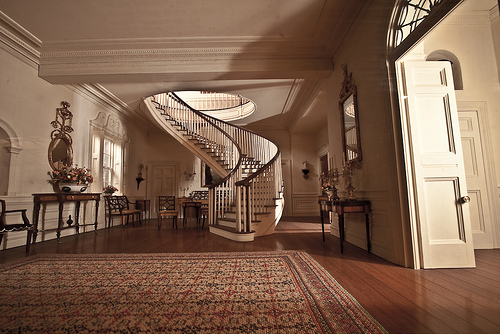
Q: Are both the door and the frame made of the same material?
A: No, the door is made of wood and the frame is made of metal.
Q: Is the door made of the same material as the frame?
A: No, the door is made of wood and the frame is made of metal.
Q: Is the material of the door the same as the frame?
A: No, the door is made of wood and the frame is made of metal.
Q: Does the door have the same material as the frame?
A: No, the door is made of wood and the frame is made of metal.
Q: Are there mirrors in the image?
A: Yes, there is a mirror.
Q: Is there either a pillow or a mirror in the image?
A: Yes, there is a mirror.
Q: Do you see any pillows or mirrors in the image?
A: Yes, there is a mirror.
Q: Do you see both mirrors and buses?
A: No, there is a mirror but no buses.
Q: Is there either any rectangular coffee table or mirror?
A: Yes, there is a rectangular mirror.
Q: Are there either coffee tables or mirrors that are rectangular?
A: Yes, the mirror is rectangular.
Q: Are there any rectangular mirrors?
A: Yes, there is a rectangular mirror.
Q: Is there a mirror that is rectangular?
A: Yes, there is a mirror that is rectangular.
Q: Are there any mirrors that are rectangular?
A: Yes, there is a mirror that is rectangular.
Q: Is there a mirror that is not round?
A: Yes, there is a rectangular mirror.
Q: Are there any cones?
A: No, there are no cones.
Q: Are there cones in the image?
A: No, there are no cones.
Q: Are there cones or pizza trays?
A: No, there are no cones or pizza trays.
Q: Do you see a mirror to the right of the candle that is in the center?
A: Yes, there is a mirror to the right of the candle.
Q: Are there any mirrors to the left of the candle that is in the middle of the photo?
A: No, the mirror is to the right of the candle.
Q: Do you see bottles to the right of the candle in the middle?
A: No, there is a mirror to the right of the candle.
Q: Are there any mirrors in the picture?
A: Yes, there is a mirror.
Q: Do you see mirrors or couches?
A: Yes, there is a mirror.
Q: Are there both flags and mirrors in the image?
A: No, there is a mirror but no flags.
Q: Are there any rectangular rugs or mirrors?
A: Yes, there is a rectangular mirror.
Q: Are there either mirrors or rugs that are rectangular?
A: Yes, the mirror is rectangular.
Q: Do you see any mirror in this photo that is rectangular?
A: Yes, there is a rectangular mirror.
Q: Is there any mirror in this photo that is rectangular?
A: Yes, there is a mirror that is rectangular.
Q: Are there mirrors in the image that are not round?
A: Yes, there is a rectangular mirror.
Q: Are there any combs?
A: No, there are no combs.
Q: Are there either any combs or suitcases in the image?
A: No, there are no combs or suitcases.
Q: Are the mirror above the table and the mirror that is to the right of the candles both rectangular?
A: Yes, both the mirror and the mirror are rectangular.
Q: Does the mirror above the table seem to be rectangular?
A: Yes, the mirror is rectangular.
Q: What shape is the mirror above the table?
A: The mirror is rectangular.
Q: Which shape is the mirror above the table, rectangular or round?
A: The mirror is rectangular.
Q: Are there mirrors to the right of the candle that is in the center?
A: Yes, there is a mirror to the right of the candle.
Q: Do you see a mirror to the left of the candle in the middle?
A: No, the mirror is to the right of the candle.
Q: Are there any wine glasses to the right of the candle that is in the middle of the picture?
A: No, there is a mirror to the right of the candle.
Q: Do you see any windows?
A: Yes, there is a window.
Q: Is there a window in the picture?
A: Yes, there is a window.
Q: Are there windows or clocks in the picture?
A: Yes, there is a window.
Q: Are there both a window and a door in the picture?
A: Yes, there are both a window and a door.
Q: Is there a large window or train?
A: Yes, there is a large window.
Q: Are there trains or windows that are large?
A: Yes, the window is large.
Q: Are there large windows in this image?
A: Yes, there is a large window.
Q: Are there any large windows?
A: Yes, there is a large window.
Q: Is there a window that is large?
A: Yes, there is a window that is large.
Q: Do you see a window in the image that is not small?
A: Yes, there is a large window.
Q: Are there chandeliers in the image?
A: No, there are no chandeliers.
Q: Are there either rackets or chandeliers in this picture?
A: No, there are no chandeliers or rackets.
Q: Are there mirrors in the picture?
A: Yes, there is a mirror.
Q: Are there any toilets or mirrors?
A: Yes, there is a mirror.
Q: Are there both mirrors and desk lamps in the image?
A: No, there is a mirror but no desk lamps.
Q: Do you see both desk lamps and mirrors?
A: No, there is a mirror but no desk lamps.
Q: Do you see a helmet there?
A: No, there are no helmets.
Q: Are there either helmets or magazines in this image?
A: No, there are no helmets or magazines.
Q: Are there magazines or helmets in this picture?
A: No, there are no helmets or magazines.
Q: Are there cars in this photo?
A: No, there are no cars.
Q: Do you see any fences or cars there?
A: No, there are no cars or fences.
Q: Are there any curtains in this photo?
A: No, there are no curtains.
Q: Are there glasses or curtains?
A: No, there are no curtains or glasses.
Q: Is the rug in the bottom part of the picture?
A: Yes, the rug is in the bottom of the image.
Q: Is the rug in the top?
A: No, the rug is in the bottom of the image.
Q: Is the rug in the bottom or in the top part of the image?
A: The rug is in the bottom of the image.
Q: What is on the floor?
A: The rug is on the floor.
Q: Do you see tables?
A: Yes, there is a table.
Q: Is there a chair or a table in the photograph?
A: Yes, there is a table.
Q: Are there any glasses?
A: No, there are no glasses.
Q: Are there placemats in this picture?
A: No, there are no placemats.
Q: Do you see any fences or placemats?
A: No, there are no placemats or fences.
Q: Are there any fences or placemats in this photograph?
A: No, there are no placemats or fences.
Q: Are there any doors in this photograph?
A: Yes, there is a door.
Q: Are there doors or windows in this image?
A: Yes, there is a door.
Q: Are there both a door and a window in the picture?
A: Yes, there are both a door and a window.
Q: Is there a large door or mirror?
A: Yes, there is a large door.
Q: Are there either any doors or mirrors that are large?
A: Yes, the door is large.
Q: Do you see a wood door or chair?
A: Yes, there is a wood door.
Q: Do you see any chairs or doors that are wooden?
A: Yes, the door is wooden.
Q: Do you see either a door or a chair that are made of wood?
A: Yes, the door is made of wood.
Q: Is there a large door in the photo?
A: Yes, there is a large door.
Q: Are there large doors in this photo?
A: Yes, there is a large door.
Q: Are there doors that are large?
A: Yes, there is a door that is large.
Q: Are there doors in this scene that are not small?
A: Yes, there is a large door.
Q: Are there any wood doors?
A: Yes, there is a wood door.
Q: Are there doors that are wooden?
A: Yes, there is a door that is wooden.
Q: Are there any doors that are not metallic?
A: Yes, there is a wooden door.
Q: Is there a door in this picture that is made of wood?
A: Yes, there is a door that is made of wood.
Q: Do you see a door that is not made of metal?
A: Yes, there is a door that is made of wood.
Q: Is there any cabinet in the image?
A: No, there are no cabinets.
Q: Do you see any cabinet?
A: No, there are no cabinets.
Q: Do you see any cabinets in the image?
A: No, there are no cabinets.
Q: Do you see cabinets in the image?
A: No, there are no cabinets.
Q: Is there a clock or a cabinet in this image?
A: No, there are no cabinets or clocks.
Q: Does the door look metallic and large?
A: No, the door is large but wooden.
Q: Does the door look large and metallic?
A: No, the door is large but wooden.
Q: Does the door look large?
A: Yes, the door is large.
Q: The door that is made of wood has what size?
A: The door is large.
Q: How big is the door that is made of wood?
A: The door is large.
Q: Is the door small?
A: No, the door is large.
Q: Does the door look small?
A: No, the door is large.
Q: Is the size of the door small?
A: No, the door is large.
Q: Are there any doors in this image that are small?
A: No, there is a door but it is large.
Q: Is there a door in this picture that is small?
A: No, there is a door but it is large.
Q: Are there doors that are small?
A: No, there is a door but it is large.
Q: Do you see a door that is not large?
A: No, there is a door but it is large.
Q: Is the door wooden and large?
A: Yes, the door is wooden and large.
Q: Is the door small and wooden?
A: No, the door is wooden but large.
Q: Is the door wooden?
A: Yes, the door is wooden.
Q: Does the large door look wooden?
A: Yes, the door is wooden.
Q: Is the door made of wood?
A: Yes, the door is made of wood.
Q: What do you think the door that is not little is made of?
A: The door is made of wood.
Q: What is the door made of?
A: The door is made of wood.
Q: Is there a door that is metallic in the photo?
A: No, there is a door but it is wooden.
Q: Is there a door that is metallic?
A: No, there is a door but it is wooden.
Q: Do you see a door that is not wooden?
A: No, there is a door but it is wooden.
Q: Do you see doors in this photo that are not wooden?
A: No, there is a door but it is wooden.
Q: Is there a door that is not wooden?
A: No, there is a door but it is wooden.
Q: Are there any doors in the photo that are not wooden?
A: No, there is a door but it is wooden.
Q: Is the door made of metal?
A: No, the door is made of wood.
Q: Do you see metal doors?
A: No, there is a door but it is made of wood.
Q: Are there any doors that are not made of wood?
A: No, there is a door but it is made of wood.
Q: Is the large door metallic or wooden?
A: The door is wooden.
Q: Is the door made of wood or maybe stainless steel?
A: The door is made of wood.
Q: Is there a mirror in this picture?
A: Yes, there is a mirror.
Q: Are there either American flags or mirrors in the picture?
A: Yes, there is a mirror.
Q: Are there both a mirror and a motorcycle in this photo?
A: No, there is a mirror but no motorcycles.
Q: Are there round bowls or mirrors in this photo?
A: Yes, there is a round mirror.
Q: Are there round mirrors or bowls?
A: Yes, there is a round mirror.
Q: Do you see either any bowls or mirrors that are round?
A: Yes, the mirror is round.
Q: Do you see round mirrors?
A: Yes, there is a round mirror.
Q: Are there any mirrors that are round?
A: Yes, there is a mirror that is round.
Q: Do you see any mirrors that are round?
A: Yes, there is a mirror that is round.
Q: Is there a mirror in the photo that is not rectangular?
A: Yes, there is a round mirror.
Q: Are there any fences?
A: No, there are no fences.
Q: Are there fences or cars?
A: No, there are no fences or cars.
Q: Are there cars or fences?
A: No, there are no fences or cars.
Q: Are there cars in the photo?
A: No, there are no cars.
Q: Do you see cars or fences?
A: No, there are no cars or fences.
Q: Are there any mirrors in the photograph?
A: Yes, there is a mirror.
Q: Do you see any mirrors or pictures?
A: Yes, there is a mirror.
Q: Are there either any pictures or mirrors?
A: Yes, there is a mirror.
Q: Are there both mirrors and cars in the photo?
A: No, there is a mirror but no cars.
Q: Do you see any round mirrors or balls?
A: Yes, there is a round mirror.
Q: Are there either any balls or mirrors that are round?
A: Yes, the mirror is round.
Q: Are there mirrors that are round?
A: Yes, there is a mirror that is round.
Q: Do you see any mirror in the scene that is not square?
A: Yes, there is a round mirror.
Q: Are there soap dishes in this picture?
A: No, there are no soap dishes.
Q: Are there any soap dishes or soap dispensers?
A: No, there are no soap dishes or soap dispensers.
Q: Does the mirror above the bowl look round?
A: Yes, the mirror is round.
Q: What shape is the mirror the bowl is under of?
A: The mirror is round.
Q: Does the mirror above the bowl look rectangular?
A: No, the mirror is round.